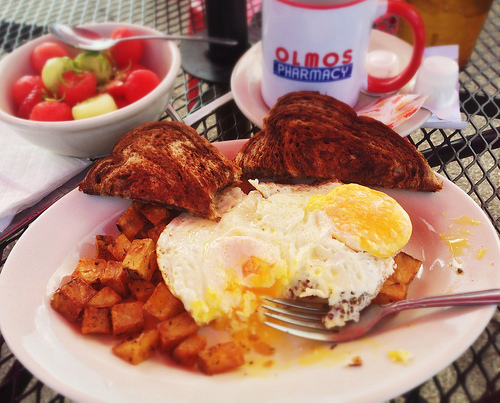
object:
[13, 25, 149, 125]
salad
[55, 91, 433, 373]
breakfast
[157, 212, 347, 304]
sunny side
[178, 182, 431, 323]
eggs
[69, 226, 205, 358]
seasoned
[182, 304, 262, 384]
potatoes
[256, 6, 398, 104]
beverage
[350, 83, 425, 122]
sweetener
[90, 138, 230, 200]
crispy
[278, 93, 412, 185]
toast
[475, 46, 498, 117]
table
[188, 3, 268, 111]
chair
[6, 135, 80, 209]
napkin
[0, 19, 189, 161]
bowl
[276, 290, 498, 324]
fork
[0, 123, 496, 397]
plate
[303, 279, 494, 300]
right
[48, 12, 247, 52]
spoon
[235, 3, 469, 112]
cup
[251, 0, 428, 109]
coffee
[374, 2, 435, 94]
red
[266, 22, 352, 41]
white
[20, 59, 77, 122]
tomatoes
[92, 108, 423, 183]
slices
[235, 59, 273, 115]
saucer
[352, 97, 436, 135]
packs